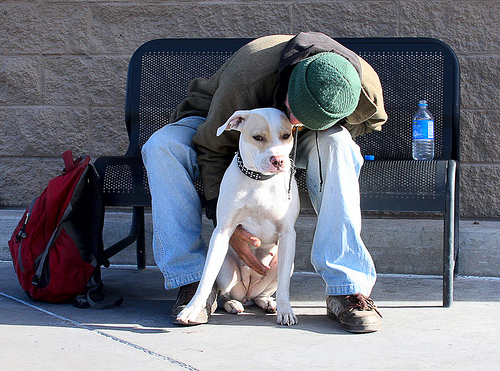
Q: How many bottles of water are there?
A: One.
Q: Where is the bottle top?
A: To the left of the bottle.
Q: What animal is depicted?
A: A dog.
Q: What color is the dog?
A: White and tan.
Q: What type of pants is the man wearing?
A: Jeans.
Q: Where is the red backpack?
A: Leaning against the left side of the bench.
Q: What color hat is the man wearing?
A: Green.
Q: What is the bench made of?
A: Metal.